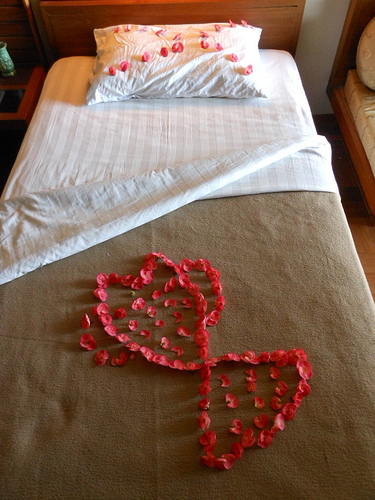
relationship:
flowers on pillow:
[109, 19, 253, 76] [84, 23, 270, 108]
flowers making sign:
[80, 251, 312, 470] [62, 242, 333, 479]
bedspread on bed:
[16, 182, 362, 489] [8, 41, 362, 481]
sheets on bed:
[32, 55, 317, 187] [8, 41, 362, 481]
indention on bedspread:
[10, 382, 97, 459] [16, 182, 362, 489]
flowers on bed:
[80, 251, 312, 470] [8, 41, 362, 481]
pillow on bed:
[86, 22, 268, 106] [8, 41, 362, 481]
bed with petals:
[8, 41, 362, 481] [106, 17, 275, 85]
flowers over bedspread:
[80, 251, 312, 470] [0, 192, 375, 500]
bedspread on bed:
[0, 192, 375, 500] [8, 41, 362, 481]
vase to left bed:
[0, 43, 16, 76] [8, 41, 362, 481]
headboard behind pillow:
[34, 0, 305, 56] [86, 22, 268, 106]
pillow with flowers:
[86, 22, 268, 106] [104, 17, 276, 84]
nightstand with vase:
[0, 67, 46, 126] [0, 36, 19, 81]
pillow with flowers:
[86, 22, 268, 106] [105, 18, 267, 88]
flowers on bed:
[80, 251, 312, 470] [0, 21, 370, 498]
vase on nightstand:
[0, 43, 16, 76] [0, 61, 46, 137]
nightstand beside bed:
[0, 61, 46, 137] [0, 21, 370, 498]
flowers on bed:
[76, 250, 312, 471] [0, 21, 370, 498]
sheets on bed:
[0, 49, 340, 286] [0, 21, 370, 498]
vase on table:
[0, 41, 17, 79] [0, 64, 46, 132]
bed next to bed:
[325, 0, 373, 219] [0, 21, 370, 498]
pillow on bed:
[87, 19, 270, 104] [0, 21, 370, 498]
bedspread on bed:
[0, 192, 375, 500] [0, 21, 370, 498]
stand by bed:
[0, 10, 38, 113] [0, 21, 370, 498]